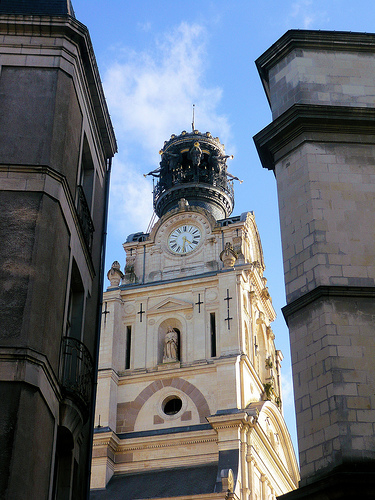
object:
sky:
[123, 37, 210, 73]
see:
[136, 95, 155, 122]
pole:
[191, 101, 196, 135]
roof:
[160, 131, 228, 142]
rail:
[54, 335, 97, 418]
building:
[0, 0, 119, 499]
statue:
[161, 326, 178, 364]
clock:
[165, 222, 202, 256]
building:
[90, 102, 301, 498]